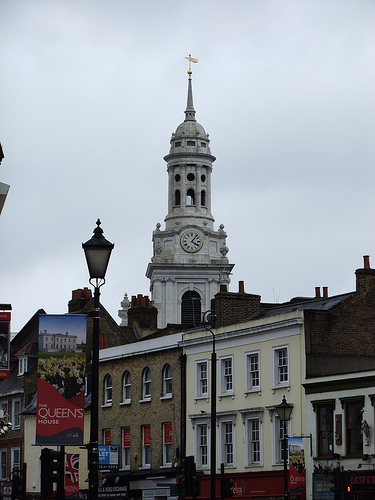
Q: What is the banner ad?
A: For The Queen's House.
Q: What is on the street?
A: Street light.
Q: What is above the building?
A: The clock tower.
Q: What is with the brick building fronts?
A: White.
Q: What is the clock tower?
A: White and gray.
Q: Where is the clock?
A: On the building.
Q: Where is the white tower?
A: Behind the buildings.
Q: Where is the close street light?
A: In front of the buildings.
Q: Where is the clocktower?
A: In the sky.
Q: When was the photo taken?
A: Daytime.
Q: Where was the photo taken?
A: In front of buildings.